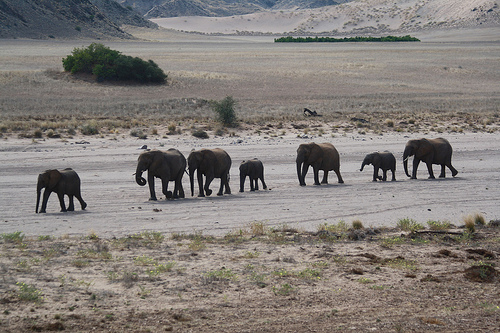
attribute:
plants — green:
[57, 39, 173, 88]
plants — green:
[59, 42, 168, 88]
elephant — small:
[359, 147, 399, 182]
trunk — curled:
[132, 170, 148, 184]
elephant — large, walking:
[292, 138, 345, 188]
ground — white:
[211, 197, 324, 223]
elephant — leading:
[31, 168, 87, 217]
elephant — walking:
[25, 163, 87, 213]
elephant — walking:
[132, 146, 187, 203]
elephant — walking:
[189, 147, 234, 195]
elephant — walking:
[239, 158, 268, 195]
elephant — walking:
[356, 149, 400, 179]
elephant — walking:
[395, 136, 459, 183]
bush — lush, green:
[58, 38, 174, 86]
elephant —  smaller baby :
[237, 156, 271, 200]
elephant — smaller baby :
[359, 148, 413, 211]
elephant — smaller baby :
[234, 149, 264, 201]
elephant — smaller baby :
[234, 147, 275, 197]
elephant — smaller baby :
[233, 151, 265, 197]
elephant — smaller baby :
[235, 157, 276, 189]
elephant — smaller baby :
[231, 160, 274, 198]